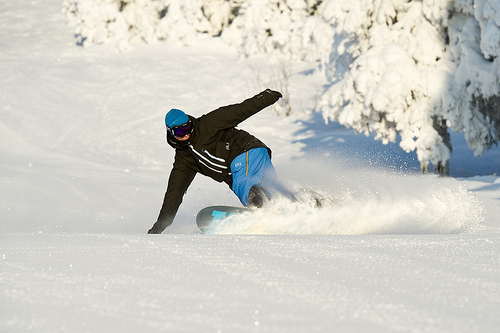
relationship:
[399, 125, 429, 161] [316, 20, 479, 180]
snow on trees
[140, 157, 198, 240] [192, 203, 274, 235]
arm of snowboarder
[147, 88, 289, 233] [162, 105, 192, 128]
man wearing blue cap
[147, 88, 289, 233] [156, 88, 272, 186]
man wearing black jacket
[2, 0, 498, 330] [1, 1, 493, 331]
snow on ground